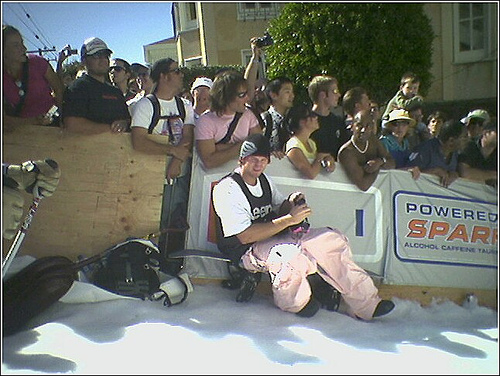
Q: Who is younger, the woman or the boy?
A: The boy is younger than the woman.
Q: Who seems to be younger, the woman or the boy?
A: The boy is younger than the woman.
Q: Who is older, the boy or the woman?
A: The woman is older than the boy.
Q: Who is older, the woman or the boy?
A: The woman is older than the boy.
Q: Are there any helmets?
A: No, there are no helmets.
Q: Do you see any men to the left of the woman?
A: Yes, there is a man to the left of the woman.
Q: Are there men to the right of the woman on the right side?
A: No, the man is to the left of the woman.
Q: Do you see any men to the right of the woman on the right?
A: No, the man is to the left of the woman.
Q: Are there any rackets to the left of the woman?
A: No, there is a man to the left of the woman.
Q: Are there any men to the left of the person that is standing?
A: Yes, there is a man to the left of the person.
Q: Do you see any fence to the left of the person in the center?
A: No, there is a man to the left of the person.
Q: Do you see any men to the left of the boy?
A: Yes, there is a man to the left of the boy.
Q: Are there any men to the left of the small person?
A: Yes, there is a man to the left of the boy.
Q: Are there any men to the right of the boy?
A: No, the man is to the left of the boy.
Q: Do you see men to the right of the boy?
A: No, the man is to the left of the boy.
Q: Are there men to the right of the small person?
A: No, the man is to the left of the boy.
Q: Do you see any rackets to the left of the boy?
A: No, there is a man to the left of the boy.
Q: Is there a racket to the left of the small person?
A: No, there is a man to the left of the boy.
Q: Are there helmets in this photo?
A: No, there are no helmets.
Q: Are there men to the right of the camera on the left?
A: Yes, there is a man to the right of the camera.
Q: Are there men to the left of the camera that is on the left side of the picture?
A: No, the man is to the right of the camera.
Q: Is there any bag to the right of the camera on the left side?
A: No, there is a man to the right of the camera.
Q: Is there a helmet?
A: No, there are no helmets.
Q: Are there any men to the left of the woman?
A: Yes, there is a man to the left of the woman.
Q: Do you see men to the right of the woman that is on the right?
A: No, the man is to the left of the woman.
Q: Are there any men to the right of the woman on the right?
A: No, the man is to the left of the woman.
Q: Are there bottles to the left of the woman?
A: No, there is a man to the left of the woman.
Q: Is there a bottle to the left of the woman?
A: No, there is a man to the left of the woman.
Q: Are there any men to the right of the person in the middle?
A: Yes, there is a man to the right of the person.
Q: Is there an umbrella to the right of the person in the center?
A: No, there is a man to the right of the person.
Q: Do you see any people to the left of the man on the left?
A: Yes, there is a person to the left of the man.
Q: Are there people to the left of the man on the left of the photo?
A: Yes, there is a person to the left of the man.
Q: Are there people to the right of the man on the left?
A: No, the person is to the left of the man.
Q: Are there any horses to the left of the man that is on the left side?
A: No, there is a person to the left of the man.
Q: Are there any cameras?
A: Yes, there is a camera.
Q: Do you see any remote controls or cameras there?
A: Yes, there is a camera.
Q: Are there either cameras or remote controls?
A: Yes, there is a camera.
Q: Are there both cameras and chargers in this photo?
A: No, there is a camera but no chargers.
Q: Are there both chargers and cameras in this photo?
A: No, there is a camera but no chargers.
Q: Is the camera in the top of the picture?
A: Yes, the camera is in the top of the image.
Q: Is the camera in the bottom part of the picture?
A: No, the camera is in the top of the image.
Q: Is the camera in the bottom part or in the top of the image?
A: The camera is in the top of the image.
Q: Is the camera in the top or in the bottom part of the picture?
A: The camera is in the top of the image.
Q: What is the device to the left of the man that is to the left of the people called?
A: The device is a camera.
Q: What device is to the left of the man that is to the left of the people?
A: The device is a camera.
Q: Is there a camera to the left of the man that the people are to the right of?
A: Yes, there is a camera to the left of the man.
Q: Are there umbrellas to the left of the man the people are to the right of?
A: No, there is a camera to the left of the man.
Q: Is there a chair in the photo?
A: No, there are no chairs.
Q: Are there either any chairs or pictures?
A: No, there are no chairs or pictures.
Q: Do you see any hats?
A: Yes, there is a hat.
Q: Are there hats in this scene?
A: Yes, there is a hat.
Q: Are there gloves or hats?
A: Yes, there is a hat.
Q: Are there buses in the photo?
A: No, there are no buses.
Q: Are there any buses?
A: No, there are no buses.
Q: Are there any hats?
A: Yes, there is a hat.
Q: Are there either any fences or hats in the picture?
A: Yes, there is a hat.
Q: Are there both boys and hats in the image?
A: Yes, there are both a hat and a boy.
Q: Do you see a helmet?
A: No, there are no helmets.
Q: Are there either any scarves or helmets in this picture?
A: No, there are no helmets or scarves.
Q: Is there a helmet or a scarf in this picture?
A: No, there are no helmets or scarves.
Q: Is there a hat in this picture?
A: Yes, there is a hat.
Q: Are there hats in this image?
A: Yes, there is a hat.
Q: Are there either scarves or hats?
A: Yes, there is a hat.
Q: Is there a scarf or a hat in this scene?
A: Yes, there is a hat.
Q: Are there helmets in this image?
A: No, there are no helmets.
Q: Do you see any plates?
A: No, there are no plates.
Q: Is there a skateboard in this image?
A: No, there are no skateboards.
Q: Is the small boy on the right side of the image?
A: Yes, the boy is on the right of the image.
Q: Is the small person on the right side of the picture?
A: Yes, the boy is on the right of the image.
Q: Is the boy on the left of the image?
A: No, the boy is on the right of the image.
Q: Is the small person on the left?
A: No, the boy is on the right of the image.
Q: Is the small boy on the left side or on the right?
A: The boy is on the right of the image.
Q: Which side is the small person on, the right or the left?
A: The boy is on the right of the image.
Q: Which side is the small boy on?
A: The boy is on the right of the image.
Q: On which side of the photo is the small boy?
A: The boy is on the right of the image.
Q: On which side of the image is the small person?
A: The boy is on the right of the image.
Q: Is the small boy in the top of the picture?
A: Yes, the boy is in the top of the image.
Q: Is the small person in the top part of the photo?
A: Yes, the boy is in the top of the image.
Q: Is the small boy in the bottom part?
A: No, the boy is in the top of the image.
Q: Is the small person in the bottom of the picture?
A: No, the boy is in the top of the image.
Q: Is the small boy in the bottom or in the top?
A: The boy is in the top of the image.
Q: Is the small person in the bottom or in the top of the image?
A: The boy is in the top of the image.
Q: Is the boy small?
A: Yes, the boy is small.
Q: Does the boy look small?
A: Yes, the boy is small.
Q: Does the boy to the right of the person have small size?
A: Yes, the boy is small.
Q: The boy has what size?
A: The boy is small.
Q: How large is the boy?
A: The boy is small.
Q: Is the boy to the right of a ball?
A: No, the boy is to the right of a man.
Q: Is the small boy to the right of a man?
A: Yes, the boy is to the right of a man.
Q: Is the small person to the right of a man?
A: Yes, the boy is to the right of a man.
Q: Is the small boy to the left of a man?
A: No, the boy is to the right of a man.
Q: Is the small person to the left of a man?
A: No, the boy is to the right of a man.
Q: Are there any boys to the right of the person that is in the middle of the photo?
A: Yes, there is a boy to the right of the person.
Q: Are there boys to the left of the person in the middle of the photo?
A: No, the boy is to the right of the person.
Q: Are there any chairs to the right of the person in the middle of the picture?
A: No, there is a boy to the right of the person.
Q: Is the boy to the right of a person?
A: Yes, the boy is to the right of a person.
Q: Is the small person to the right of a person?
A: Yes, the boy is to the right of a person.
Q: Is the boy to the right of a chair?
A: No, the boy is to the right of a person.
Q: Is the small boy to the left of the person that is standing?
A: No, the boy is to the right of the person.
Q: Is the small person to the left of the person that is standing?
A: No, the boy is to the right of the person.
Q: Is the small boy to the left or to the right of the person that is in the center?
A: The boy is to the right of the person.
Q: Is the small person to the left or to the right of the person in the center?
A: The boy is to the right of the person.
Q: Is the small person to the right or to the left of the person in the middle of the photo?
A: The boy is to the right of the person.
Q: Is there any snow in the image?
A: Yes, there is snow.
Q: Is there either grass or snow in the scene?
A: Yes, there is snow.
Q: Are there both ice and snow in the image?
A: No, there is snow but no ice.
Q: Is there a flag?
A: No, there are no flags.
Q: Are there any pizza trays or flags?
A: No, there are no flags or pizza trays.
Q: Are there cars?
A: No, there are no cars.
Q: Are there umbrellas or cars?
A: No, there are no cars or umbrellas.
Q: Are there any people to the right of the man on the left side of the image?
A: Yes, there are people to the right of the man.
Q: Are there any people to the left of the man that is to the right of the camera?
A: No, the people are to the right of the man.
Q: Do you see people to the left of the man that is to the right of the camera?
A: No, the people are to the right of the man.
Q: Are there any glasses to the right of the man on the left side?
A: No, there are people to the right of the man.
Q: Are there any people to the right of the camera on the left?
A: Yes, there are people to the right of the camera.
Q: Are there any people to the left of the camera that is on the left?
A: No, the people are to the right of the camera.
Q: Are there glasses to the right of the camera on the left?
A: No, there are people to the right of the camera.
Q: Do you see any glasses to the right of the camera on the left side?
A: No, there are people to the right of the camera.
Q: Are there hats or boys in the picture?
A: Yes, there is a hat.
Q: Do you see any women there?
A: Yes, there is a woman.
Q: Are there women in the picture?
A: Yes, there is a woman.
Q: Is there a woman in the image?
A: Yes, there is a woman.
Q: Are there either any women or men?
A: Yes, there is a woman.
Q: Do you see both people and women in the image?
A: Yes, there are both a woman and a person.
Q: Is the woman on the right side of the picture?
A: Yes, the woman is on the right of the image.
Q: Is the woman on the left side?
A: No, the woman is on the right of the image.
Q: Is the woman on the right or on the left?
A: The woman is on the right of the image.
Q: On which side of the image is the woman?
A: The woman is on the right of the image.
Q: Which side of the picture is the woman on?
A: The woman is on the right of the image.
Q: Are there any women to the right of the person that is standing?
A: Yes, there is a woman to the right of the person.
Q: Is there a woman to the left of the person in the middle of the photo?
A: No, the woman is to the right of the person.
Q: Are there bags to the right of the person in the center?
A: No, there is a woman to the right of the person.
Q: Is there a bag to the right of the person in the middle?
A: No, there is a woman to the right of the person.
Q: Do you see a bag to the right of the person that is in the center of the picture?
A: No, there is a woman to the right of the person.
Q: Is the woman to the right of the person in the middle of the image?
A: Yes, the woman is to the right of the person.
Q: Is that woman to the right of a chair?
A: No, the woman is to the right of the person.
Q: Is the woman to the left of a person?
A: No, the woman is to the right of a person.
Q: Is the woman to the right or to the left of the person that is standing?
A: The woman is to the right of the person.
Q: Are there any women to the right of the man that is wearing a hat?
A: Yes, there is a woman to the right of the man.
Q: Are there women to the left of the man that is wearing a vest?
A: No, the woman is to the right of the man.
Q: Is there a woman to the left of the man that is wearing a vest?
A: No, the woman is to the right of the man.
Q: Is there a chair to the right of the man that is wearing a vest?
A: No, there is a woman to the right of the man.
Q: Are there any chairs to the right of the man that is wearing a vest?
A: No, there is a woman to the right of the man.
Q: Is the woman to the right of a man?
A: Yes, the woman is to the right of a man.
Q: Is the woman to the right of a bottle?
A: No, the woman is to the right of a man.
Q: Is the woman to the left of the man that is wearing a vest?
A: No, the woman is to the right of the man.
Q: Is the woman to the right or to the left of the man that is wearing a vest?
A: The woman is to the right of the man.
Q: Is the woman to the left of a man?
A: No, the woman is to the right of a man.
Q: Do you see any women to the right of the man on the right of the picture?
A: Yes, there is a woman to the right of the man.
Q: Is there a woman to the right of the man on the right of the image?
A: Yes, there is a woman to the right of the man.